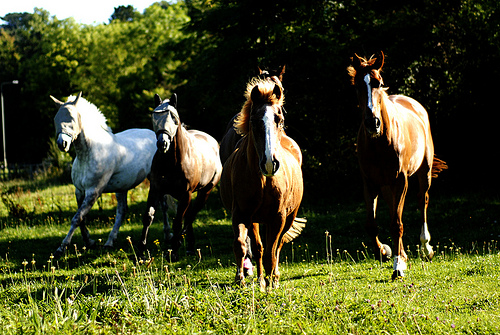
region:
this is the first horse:
[320, 39, 457, 289]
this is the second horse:
[202, 56, 321, 303]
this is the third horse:
[114, 77, 253, 255]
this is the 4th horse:
[33, 84, 177, 292]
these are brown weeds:
[113, 245, 205, 332]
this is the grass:
[430, 275, 468, 317]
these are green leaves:
[94, 42, 146, 88]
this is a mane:
[223, 62, 290, 141]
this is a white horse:
[28, 78, 186, 250]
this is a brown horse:
[172, 56, 340, 321]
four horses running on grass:
[41, 58, 472, 296]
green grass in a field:
[40, 295, 480, 325]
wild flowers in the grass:
[107, 225, 202, 276]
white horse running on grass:
[27, 80, 162, 255]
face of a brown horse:
[233, 62, 289, 174]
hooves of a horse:
[369, 242, 419, 291]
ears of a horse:
[349, 48, 389, 70]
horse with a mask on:
[142, 87, 189, 152]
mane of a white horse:
[68, 90, 117, 137]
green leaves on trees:
[18, 6, 193, 83]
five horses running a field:
[46, 45, 450, 292]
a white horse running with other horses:
[45, 89, 155, 255]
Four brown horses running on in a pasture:
[137, 51, 448, 293]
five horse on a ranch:
[2, 47, 496, 327]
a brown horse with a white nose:
[220, 77, 305, 297]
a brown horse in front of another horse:
[217, 53, 308, 290]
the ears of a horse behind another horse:
[253, 61, 286, 76]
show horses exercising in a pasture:
[47, 47, 449, 289]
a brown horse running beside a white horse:
[47, 90, 219, 259]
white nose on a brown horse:
[262, 107, 274, 177]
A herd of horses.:
[32, 51, 445, 303]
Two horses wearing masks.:
[53, 87, 197, 149]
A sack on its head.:
[43, 98, 83, 146]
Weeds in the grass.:
[29, 239, 218, 329]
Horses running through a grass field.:
[28, 43, 478, 291]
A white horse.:
[23, 72, 150, 269]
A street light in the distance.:
[0, 71, 25, 182]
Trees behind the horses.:
[2, 27, 344, 179]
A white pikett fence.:
[7, 156, 52, 173]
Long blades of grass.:
[5, 182, 60, 224]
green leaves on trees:
[83, 26, 191, 86]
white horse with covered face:
[40, 82, 164, 246]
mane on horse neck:
[225, 80, 260, 143]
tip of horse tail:
[424, 149, 458, 182]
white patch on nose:
[360, 67, 378, 118]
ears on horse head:
[248, 79, 282, 107]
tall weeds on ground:
[107, 234, 204, 328]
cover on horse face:
[146, 103, 183, 148]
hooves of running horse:
[362, 222, 434, 284]